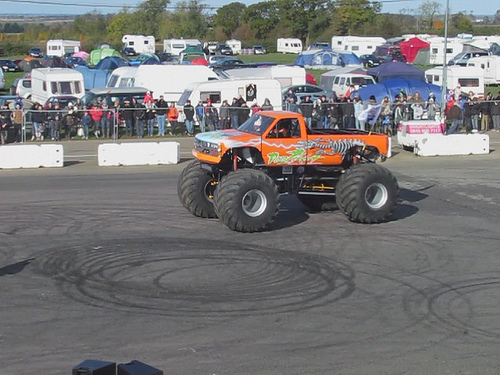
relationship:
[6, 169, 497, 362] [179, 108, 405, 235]
arena for monster truck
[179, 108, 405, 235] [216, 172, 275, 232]
truck has tire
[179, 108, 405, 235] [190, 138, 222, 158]
truck has grill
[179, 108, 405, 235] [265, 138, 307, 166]
truck has door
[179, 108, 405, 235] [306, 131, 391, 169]
truck has bed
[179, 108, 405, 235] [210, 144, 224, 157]
truck has headlight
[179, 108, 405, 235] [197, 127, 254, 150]
truck has hood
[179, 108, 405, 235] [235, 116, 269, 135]
truck has windshield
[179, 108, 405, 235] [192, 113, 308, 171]
truck has cab